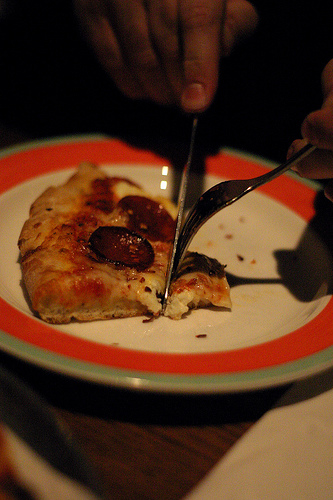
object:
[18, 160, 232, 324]
pizza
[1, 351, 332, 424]
shadow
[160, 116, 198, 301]
knife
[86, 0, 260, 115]
hand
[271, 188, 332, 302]
shadow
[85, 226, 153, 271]
pepperoni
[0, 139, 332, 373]
stripe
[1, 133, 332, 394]
plate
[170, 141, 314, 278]
fork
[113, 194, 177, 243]
pepperoni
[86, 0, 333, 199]
human